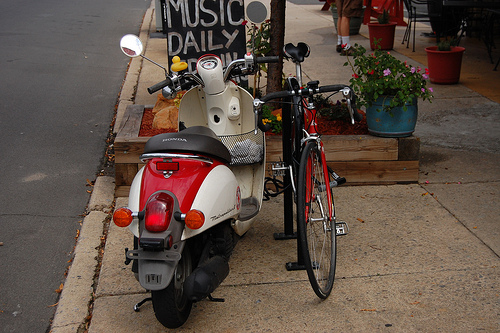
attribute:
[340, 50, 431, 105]
plant — small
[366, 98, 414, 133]
pot — blue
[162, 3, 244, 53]
writing — white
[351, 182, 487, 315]
sidewalk — concrete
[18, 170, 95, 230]
pavement — black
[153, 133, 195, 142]
writing — small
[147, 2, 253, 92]
sign — black